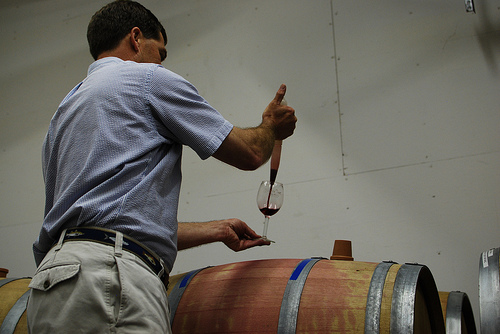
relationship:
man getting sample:
[28, 17, 267, 328] [266, 167, 277, 207]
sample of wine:
[266, 167, 277, 207] [249, 180, 290, 223]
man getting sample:
[28, 17, 267, 328] [257, 164, 280, 206]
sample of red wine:
[257, 164, 280, 206] [253, 140, 289, 245]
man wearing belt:
[28, 17, 267, 328] [46, 220, 179, 294]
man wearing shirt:
[28, 17, 267, 328] [36, 76, 236, 260]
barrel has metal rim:
[164, 254, 448, 331] [392, 262, 447, 332]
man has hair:
[28, 17, 267, 328] [80, 0, 167, 57]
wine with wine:
[259, 181, 280, 215] [259, 180, 281, 215]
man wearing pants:
[28, 17, 267, 328] [22, 224, 170, 332]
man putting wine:
[28, 17, 267, 328] [266, 178, 270, 208]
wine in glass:
[266, 178, 270, 208] [256, 176, 283, 241]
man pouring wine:
[28, 17, 267, 328] [260, 181, 279, 213]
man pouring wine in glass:
[28, 17, 267, 328] [252, 177, 283, 244]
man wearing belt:
[28, 17, 267, 328] [26, 207, 186, 285]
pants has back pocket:
[22, 224, 170, 332] [23, 262, 83, 329]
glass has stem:
[255, 175, 286, 245] [257, 214, 269, 236]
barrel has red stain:
[164, 254, 448, 331] [173, 260, 354, 332]